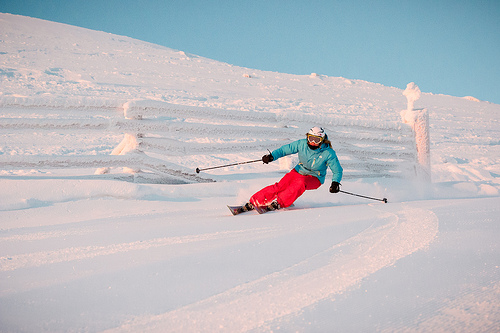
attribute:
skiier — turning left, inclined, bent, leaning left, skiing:
[228, 124, 343, 218]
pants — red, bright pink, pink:
[247, 169, 322, 211]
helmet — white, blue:
[307, 126, 327, 140]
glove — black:
[328, 182, 341, 194]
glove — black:
[261, 151, 272, 164]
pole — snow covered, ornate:
[396, 80, 435, 193]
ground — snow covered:
[0, 10, 499, 331]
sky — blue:
[1, 1, 498, 110]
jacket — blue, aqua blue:
[262, 135, 346, 188]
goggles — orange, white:
[306, 135, 323, 144]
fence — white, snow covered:
[1, 78, 440, 197]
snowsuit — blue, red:
[246, 137, 342, 208]